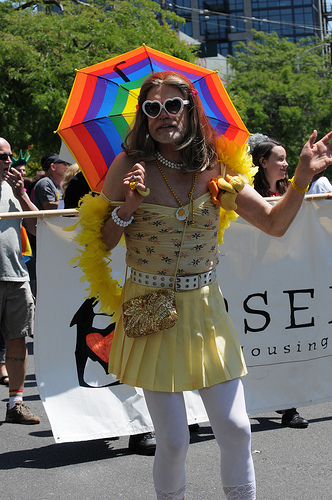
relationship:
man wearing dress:
[89, 68, 331, 500] [91, 161, 248, 393]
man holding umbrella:
[89, 68, 331, 500] [53, 43, 251, 196]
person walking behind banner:
[0, 136, 41, 429] [36, 196, 331, 444]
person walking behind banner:
[26, 153, 73, 303] [36, 196, 331, 444]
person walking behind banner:
[248, 138, 289, 198] [36, 196, 331, 444]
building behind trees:
[34, 0, 331, 105] [2, 3, 212, 180]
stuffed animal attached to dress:
[206, 171, 244, 212] [91, 161, 248, 393]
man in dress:
[89, 68, 331, 500] [91, 161, 248, 393]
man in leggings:
[89, 68, 331, 500] [139, 375, 261, 499]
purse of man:
[122, 286, 179, 337] [89, 68, 331, 500]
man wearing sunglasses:
[89, 68, 331, 500] [140, 96, 191, 120]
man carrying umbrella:
[89, 68, 331, 500] [53, 43, 251, 196]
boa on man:
[71, 190, 127, 324] [89, 68, 331, 500]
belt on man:
[129, 268, 216, 291] [89, 68, 331, 500]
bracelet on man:
[108, 206, 134, 231] [89, 68, 331, 500]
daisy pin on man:
[173, 205, 189, 226] [89, 68, 331, 500]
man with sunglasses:
[89, 68, 331, 500] [140, 96, 191, 120]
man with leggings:
[89, 68, 331, 500] [139, 375, 261, 499]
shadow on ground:
[0, 430, 138, 473] [1, 317, 330, 497]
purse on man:
[122, 286, 179, 337] [89, 68, 331, 500]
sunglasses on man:
[140, 96, 191, 120] [89, 68, 331, 500]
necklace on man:
[150, 158, 198, 226] [89, 68, 331, 500]